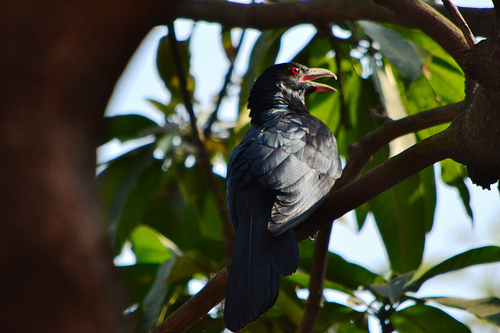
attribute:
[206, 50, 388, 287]
bird — black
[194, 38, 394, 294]
bird — black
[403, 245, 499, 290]
tree leaves — green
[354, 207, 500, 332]
leaves on tree — green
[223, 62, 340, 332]
bird — black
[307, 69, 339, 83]
beak — orange, beige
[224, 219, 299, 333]
feathers — black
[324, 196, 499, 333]
leaves — green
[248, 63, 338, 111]
head — black